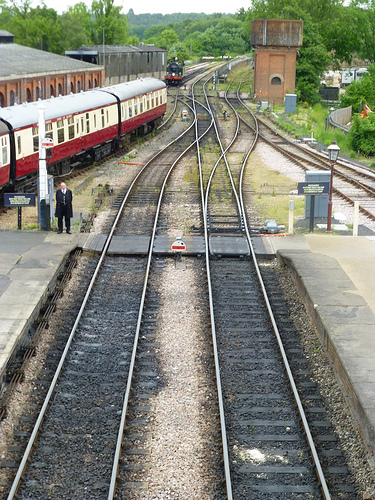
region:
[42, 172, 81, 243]
Man standing on the pavement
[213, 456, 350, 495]
Small black wooden plank of wood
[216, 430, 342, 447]
Small black plank of wood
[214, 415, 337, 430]
Small black plank of wood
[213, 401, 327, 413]
Small black plank of wood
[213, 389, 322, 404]
Small black plank of wood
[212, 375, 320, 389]
Small black plank of wood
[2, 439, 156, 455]
Small black plank of wood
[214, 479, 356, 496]
Small black plank of wood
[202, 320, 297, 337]
Small black plank of wood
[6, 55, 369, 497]
Many sets of train tracks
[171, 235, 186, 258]
White and red sign between the train tracks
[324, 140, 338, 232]
Narrow brown lamp post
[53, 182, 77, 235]
The man is standing on the station platform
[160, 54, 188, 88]
The train engine is black and red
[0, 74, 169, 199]
The train cars are white and red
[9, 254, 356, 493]
Black gravel under the train tracks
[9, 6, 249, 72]
Green trees behind the train station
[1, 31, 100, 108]
Train station with a black roof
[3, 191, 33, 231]
Blue sign with white writing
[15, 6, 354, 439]
a rural railroad station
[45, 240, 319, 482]
rails whose trains go in opposite directions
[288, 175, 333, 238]
information sign at the end of the platform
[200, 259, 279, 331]
ties and rails of the track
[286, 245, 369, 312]
station platform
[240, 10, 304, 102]
utility building along the tracks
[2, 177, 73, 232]
man standing next to a sign at the end of the platform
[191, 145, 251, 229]
single track splits into two lines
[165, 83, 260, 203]
tracks crossing each other and merging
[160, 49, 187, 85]
single car engine sits on the track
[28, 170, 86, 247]
man standing on train platform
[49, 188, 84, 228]
man wearing black suit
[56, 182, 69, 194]
man wearing white shirt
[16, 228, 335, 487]
two train tracks next to each other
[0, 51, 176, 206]
white train on tracks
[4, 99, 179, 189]
red trim on train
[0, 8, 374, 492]
black and red train in distance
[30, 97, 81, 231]
man standind next to white pole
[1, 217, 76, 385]
train platform is grey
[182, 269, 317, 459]
black gravel on train tracks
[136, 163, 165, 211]
Part of train track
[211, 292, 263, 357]
Part of train track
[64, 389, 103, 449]
Part of train track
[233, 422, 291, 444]
Part of train track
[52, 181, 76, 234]
Person standing near track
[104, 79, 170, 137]
Part of passenger train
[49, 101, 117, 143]
Part of passenger train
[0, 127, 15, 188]
Part of passenger train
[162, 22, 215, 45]
Green trees near traintracks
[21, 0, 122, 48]
Green trees near train